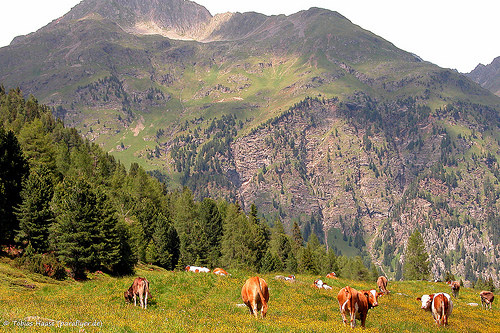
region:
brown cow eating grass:
[123, 277, 156, 309]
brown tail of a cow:
[251, 273, 270, 321]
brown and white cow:
[335, 283, 385, 328]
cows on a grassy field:
[98, 264, 498, 331]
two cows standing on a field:
[121, 274, 272, 320]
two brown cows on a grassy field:
[121, 273, 273, 318]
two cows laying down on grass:
[179, 263, 229, 275]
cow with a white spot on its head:
[334, 284, 386, 329]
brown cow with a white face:
[413, 290, 451, 329]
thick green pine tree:
[41, 167, 141, 278]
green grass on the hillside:
[29, 20, 469, 162]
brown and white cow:
[417, 292, 449, 325]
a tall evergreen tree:
[57, 181, 102, 277]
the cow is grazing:
[122, 279, 150, 306]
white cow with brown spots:
[183, 264, 208, 273]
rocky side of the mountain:
[231, 105, 485, 275]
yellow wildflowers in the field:
[271, 312, 372, 330]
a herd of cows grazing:
[126, 255, 496, 325]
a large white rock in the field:
[470, 301, 477, 308]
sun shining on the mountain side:
[130, 13, 227, 43]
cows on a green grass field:
[122, 264, 498, 327]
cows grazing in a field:
[123, 262, 496, 329]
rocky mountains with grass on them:
[3, 2, 498, 289]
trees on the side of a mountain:
[1, 84, 435, 282]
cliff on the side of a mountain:
[169, 97, 492, 279]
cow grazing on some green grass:
[123, 277, 150, 309]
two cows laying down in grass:
[274, 272, 334, 289]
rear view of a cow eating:
[241, 276, 270, 322]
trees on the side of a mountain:
[169, 116, 237, 185]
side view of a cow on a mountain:
[339, 287, 379, 326]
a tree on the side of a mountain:
[143, 212, 173, 267]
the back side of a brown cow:
[241, 276, 268, 318]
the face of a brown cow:
[363, 287, 382, 306]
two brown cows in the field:
[336, 287, 452, 329]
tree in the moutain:
[118, 141, 124, 148]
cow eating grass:
[121, 277, 154, 309]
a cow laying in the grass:
[311, 278, 334, 291]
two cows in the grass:
[121, 277, 271, 321]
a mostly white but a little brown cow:
[185, 265, 210, 275]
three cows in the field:
[417, 280, 494, 325]